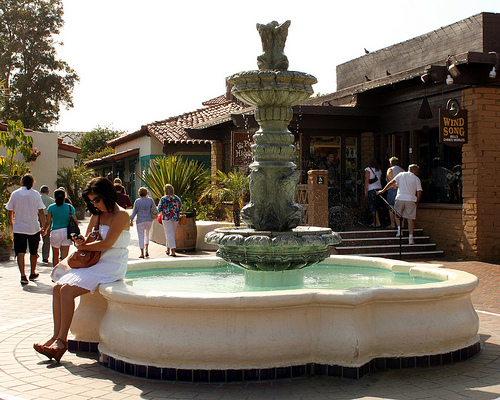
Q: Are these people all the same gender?
A: No, they are both male and female.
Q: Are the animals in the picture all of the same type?
A: Yes, all the animals are birds.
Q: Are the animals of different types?
A: No, all the animals are birds.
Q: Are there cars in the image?
A: No, there are no cars.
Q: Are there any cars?
A: No, there are no cars.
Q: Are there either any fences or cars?
A: No, there are no cars or fences.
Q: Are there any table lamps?
A: No, there are no table lamps.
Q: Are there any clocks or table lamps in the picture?
A: No, there are no table lamps or clocks.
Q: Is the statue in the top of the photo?
A: Yes, the statue is in the top of the image.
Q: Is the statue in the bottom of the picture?
A: No, the statue is in the top of the image.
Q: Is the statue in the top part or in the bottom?
A: The statue is in the top of the image.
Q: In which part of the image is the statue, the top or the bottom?
A: The statue is in the top of the image.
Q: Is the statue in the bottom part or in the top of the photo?
A: The statue is in the top of the image.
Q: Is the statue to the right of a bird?
A: No, the statue is to the left of a bird.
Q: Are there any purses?
A: Yes, there is a purse.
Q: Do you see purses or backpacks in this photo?
A: Yes, there is a purse.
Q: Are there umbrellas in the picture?
A: No, there are no umbrellas.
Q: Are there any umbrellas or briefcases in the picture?
A: No, there are no umbrellas or briefcases.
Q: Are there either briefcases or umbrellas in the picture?
A: No, there are no umbrellas or briefcases.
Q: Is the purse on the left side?
A: Yes, the purse is on the left of the image.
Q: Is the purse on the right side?
A: No, the purse is on the left of the image.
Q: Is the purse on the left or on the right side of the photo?
A: The purse is on the left of the image.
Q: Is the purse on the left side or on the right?
A: The purse is on the left of the image.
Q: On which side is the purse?
A: The purse is on the left of the image.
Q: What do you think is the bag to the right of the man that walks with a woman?
A: The bag is a purse.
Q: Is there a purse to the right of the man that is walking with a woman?
A: Yes, there is a purse to the right of the man.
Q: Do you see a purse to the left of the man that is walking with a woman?
A: No, the purse is to the right of the man.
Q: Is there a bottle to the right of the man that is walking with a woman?
A: No, there is a purse to the right of the man.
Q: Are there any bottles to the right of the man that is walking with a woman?
A: No, there is a purse to the right of the man.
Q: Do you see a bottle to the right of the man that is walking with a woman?
A: No, there is a purse to the right of the man.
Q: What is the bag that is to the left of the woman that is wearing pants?
A: The bag is a purse.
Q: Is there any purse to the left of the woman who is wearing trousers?
A: Yes, there is a purse to the left of the woman.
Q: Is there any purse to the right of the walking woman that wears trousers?
A: No, the purse is to the left of the woman.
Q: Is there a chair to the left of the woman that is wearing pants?
A: No, there is a purse to the left of the woman.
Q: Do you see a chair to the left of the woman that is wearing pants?
A: No, there is a purse to the left of the woman.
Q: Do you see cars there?
A: No, there are no cars.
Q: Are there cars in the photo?
A: No, there are no cars.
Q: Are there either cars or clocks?
A: No, there are no cars or clocks.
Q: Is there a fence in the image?
A: No, there are no fences.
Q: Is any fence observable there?
A: No, there are no fences.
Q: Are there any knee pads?
A: No, there are no knee pads.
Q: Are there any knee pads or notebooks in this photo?
A: No, there are no knee pads or notebooks.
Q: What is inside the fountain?
A: The water is inside the fountain.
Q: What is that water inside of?
A: The water is inside the fountain.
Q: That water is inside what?
A: The water is inside the fountain.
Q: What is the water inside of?
A: The water is inside the fountain.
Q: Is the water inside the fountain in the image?
A: Yes, the water is inside the fountain.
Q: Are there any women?
A: Yes, there is a woman.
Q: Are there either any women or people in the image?
A: Yes, there is a woman.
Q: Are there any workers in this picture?
A: No, there are no workers.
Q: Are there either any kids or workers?
A: No, there are no workers or kids.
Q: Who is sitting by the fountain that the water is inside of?
A: The woman is sitting by the fountain.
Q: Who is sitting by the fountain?
A: The woman is sitting by the fountain.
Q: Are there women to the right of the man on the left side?
A: Yes, there is a woman to the right of the man.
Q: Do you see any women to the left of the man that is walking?
A: No, the woman is to the right of the man.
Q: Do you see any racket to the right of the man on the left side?
A: No, there is a woman to the right of the man.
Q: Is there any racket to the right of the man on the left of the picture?
A: No, there is a woman to the right of the man.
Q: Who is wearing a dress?
A: The woman is wearing a dress.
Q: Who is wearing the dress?
A: The woman is wearing a dress.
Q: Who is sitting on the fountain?
A: The woman is sitting on the fountain.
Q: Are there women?
A: Yes, there is a woman.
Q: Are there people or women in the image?
A: Yes, there is a woman.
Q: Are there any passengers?
A: No, there are no passengers.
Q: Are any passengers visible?
A: No, there are no passengers.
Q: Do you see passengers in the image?
A: No, there are no passengers.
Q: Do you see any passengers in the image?
A: No, there are no passengers.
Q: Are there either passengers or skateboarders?
A: No, there are no passengers or skateboarders.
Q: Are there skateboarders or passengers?
A: No, there are no passengers or skateboarders.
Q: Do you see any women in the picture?
A: Yes, there is a woman.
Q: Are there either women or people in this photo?
A: Yes, there is a woman.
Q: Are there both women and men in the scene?
A: Yes, there are both a woman and a man.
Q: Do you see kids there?
A: No, there are no kids.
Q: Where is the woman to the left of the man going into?
A: The woman is going into the building.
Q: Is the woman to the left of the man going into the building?
A: Yes, the woman is going into the building.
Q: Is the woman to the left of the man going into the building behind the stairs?
A: Yes, the woman is going into the building.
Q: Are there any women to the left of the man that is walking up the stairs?
A: Yes, there is a woman to the left of the man.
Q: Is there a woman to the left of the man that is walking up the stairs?
A: Yes, there is a woman to the left of the man.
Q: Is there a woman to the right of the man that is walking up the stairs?
A: No, the woman is to the left of the man.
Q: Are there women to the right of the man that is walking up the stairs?
A: No, the woman is to the left of the man.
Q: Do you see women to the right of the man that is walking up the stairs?
A: No, the woman is to the left of the man.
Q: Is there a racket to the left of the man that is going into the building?
A: No, there is a woman to the left of the man.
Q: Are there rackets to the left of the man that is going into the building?
A: No, there is a woman to the left of the man.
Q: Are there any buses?
A: No, there are no buses.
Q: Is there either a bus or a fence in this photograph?
A: No, there are no buses or fences.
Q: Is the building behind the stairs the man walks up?
A: Yes, the building is behind the stairs.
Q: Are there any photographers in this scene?
A: No, there are no photographers.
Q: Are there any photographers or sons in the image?
A: No, there are no photographers or sons.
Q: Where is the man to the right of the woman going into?
A: The man is going into the building.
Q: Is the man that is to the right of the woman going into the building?
A: Yes, the man is going into the building.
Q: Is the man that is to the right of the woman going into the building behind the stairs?
A: Yes, the man is going into the building.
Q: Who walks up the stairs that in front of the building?
A: The man walks up the stairs.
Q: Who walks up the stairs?
A: The man walks up the stairs.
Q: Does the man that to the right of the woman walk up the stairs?
A: Yes, the man walks up the stairs.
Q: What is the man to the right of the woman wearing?
A: The man is wearing a shirt.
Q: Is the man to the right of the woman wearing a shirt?
A: Yes, the man is wearing a shirt.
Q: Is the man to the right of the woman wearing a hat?
A: No, the man is wearing a shirt.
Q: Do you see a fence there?
A: No, there are no fences.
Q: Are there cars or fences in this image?
A: No, there are no fences or cars.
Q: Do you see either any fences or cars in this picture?
A: No, there are no fences or cars.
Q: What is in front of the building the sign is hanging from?
A: The stairs are in front of the building.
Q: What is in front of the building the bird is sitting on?
A: The stairs are in front of the building.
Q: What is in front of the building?
A: The stairs are in front of the building.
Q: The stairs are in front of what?
A: The stairs are in front of the building.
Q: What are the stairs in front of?
A: The stairs are in front of the building.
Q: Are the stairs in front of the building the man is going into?
A: Yes, the stairs are in front of the building.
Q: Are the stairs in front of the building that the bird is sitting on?
A: Yes, the stairs are in front of the building.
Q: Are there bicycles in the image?
A: No, there are no bicycles.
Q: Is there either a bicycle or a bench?
A: No, there are no bicycles or benches.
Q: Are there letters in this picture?
A: Yes, there are letters.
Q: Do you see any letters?
A: Yes, there are letters.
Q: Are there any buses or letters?
A: Yes, there are letters.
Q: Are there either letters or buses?
A: Yes, there are letters.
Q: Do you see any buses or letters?
A: Yes, there are letters.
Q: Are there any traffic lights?
A: No, there are no traffic lights.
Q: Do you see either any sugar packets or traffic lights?
A: No, there are no traffic lights or sugar packets.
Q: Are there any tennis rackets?
A: No, there are no tennis rackets.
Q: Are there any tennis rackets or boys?
A: No, there are no tennis rackets or boys.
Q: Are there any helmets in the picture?
A: No, there are no helmets.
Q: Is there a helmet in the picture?
A: No, there are no helmets.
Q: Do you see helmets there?
A: No, there are no helmets.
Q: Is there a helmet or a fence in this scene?
A: No, there are no helmets or fences.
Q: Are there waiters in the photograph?
A: No, there are no waiters.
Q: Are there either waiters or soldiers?
A: No, there are no waiters or soldiers.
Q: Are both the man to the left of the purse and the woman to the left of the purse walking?
A: Yes, both the man and the woman are walking.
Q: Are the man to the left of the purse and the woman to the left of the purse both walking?
A: Yes, both the man and the woman are walking.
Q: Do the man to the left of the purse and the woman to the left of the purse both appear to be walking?
A: Yes, both the man and the woman are walking.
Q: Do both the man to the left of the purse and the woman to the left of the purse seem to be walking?
A: Yes, both the man and the woman are walking.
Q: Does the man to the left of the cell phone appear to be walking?
A: Yes, the man is walking.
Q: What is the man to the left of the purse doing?
A: The man is walking.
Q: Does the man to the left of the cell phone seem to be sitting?
A: No, the man is walking.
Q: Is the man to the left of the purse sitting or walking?
A: The man is walking.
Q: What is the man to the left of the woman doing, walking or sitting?
A: The man is walking.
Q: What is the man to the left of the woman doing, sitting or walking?
A: The man is walking.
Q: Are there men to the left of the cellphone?
A: Yes, there is a man to the left of the cellphone.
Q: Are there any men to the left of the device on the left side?
A: Yes, there is a man to the left of the cellphone.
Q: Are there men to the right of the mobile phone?
A: No, the man is to the left of the mobile phone.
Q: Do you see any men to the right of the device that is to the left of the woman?
A: No, the man is to the left of the mobile phone.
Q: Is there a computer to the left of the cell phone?
A: No, there is a man to the left of the cell phone.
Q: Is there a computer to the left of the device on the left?
A: No, there is a man to the left of the cell phone.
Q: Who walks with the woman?
A: The man walks with the woman.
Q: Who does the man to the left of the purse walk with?
A: The man walks with a woman.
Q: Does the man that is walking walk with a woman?
A: Yes, the man walks with a woman.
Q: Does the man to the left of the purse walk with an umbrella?
A: No, the man walks with a woman.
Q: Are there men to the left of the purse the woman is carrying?
A: Yes, there is a man to the left of the purse.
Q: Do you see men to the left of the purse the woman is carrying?
A: Yes, there is a man to the left of the purse.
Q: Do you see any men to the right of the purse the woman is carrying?
A: No, the man is to the left of the purse.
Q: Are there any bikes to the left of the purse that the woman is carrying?
A: No, there is a man to the left of the purse.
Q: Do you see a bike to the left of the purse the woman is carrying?
A: No, there is a man to the left of the purse.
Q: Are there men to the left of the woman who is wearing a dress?
A: Yes, there is a man to the left of the woman.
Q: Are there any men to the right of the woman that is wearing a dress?
A: No, the man is to the left of the woman.